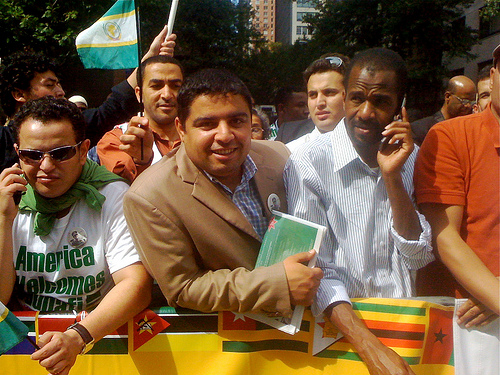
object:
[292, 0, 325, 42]
buildings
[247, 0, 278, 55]
buildings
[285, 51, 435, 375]
man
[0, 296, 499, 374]
fence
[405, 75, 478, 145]
man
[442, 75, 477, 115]
head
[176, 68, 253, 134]
brown hair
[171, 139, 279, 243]
lapel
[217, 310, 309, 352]
flag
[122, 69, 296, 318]
man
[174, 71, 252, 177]
head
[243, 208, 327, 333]
hand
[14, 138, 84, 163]
glasses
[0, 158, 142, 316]
shirt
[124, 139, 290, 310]
jacket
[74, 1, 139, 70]
flag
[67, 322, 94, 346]
watch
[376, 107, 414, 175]
hand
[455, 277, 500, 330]
hand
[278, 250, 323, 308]
hand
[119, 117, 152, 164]
hand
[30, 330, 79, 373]
hand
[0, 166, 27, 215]
hand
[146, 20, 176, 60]
hand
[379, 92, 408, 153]
cell phone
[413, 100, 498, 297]
orange shirt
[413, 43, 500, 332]
man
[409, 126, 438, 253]
shadow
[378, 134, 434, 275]
man's arm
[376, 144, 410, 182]
ground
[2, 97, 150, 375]
man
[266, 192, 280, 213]
button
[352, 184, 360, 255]
stripes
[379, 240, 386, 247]
buttons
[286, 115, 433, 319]
shirt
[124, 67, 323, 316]
person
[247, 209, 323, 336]
newspaper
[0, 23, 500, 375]
group